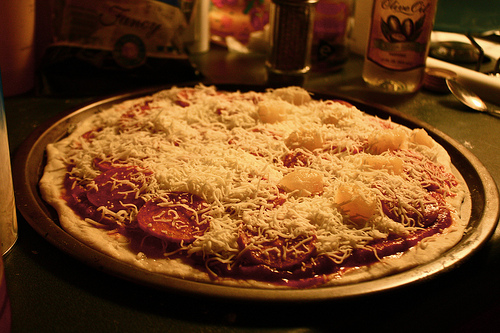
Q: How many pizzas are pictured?
A: One.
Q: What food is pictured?
A: A pizza.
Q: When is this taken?
A: Dinner time.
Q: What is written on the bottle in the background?
A: Olive oil.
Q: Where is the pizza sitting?
A: On a pan.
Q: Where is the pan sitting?
A: On the table.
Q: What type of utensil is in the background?
A: A spoon.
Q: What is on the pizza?
A: Cheese, pepperoni, and pineapple.